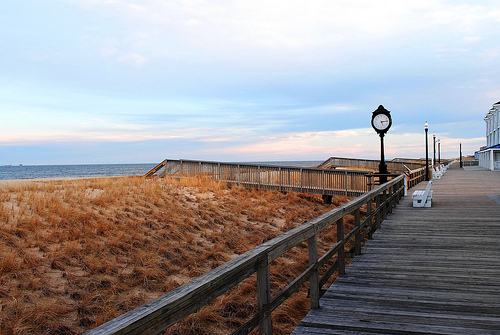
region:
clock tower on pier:
[365, 101, 391, 188]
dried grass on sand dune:
[5, 178, 317, 330]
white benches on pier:
[415, 155, 458, 210]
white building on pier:
[467, 102, 499, 170]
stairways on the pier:
[144, 151, 436, 196]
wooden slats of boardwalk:
[332, 145, 493, 332]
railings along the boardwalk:
[107, 151, 459, 333]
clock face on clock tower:
[372, 110, 389, 131]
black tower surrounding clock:
[373, 104, 389, 183]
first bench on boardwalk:
[398, 173, 435, 207]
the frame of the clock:
[368, 102, 397, 137]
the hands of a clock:
[377, 116, 391, 127]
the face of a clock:
[370, 113, 392, 132]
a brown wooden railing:
[73, 170, 411, 334]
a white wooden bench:
[406, 175, 439, 211]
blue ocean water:
[0, 157, 330, 185]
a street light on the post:
[421, 118, 432, 134]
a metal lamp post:
[421, 126, 431, 182]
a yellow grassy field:
[0, 173, 380, 334]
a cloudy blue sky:
[1, 0, 499, 165]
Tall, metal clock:
[367, 103, 390, 180]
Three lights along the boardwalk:
[423, 120, 444, 172]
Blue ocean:
[1, 160, 162, 177]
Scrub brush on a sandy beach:
[2, 170, 376, 332]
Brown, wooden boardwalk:
[87, 159, 498, 333]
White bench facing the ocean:
[411, 181, 434, 210]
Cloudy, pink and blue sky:
[0, 0, 497, 157]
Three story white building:
[473, 98, 498, 169]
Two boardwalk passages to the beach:
[137, 158, 419, 192]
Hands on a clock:
[379, 118, 388, 128]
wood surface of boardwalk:
[315, 155, 497, 333]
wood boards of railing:
[188, 176, 408, 333]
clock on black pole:
[371, 105, 396, 177]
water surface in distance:
[0, 157, 325, 182]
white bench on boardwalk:
[411, 181, 436, 213]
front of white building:
[478, 103, 497, 170]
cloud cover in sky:
[4, 2, 495, 161]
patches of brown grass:
[3, 177, 367, 331]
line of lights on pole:
[420, 119, 447, 177]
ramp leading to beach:
[160, 158, 398, 196]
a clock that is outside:
[269, 70, 428, 230]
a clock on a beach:
[326, 83, 456, 259]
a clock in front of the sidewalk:
[340, 119, 436, 259]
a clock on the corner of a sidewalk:
[261, 58, 496, 295]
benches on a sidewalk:
[391, 96, 482, 250]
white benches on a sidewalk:
[394, 97, 464, 252]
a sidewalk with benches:
[392, 86, 488, 258]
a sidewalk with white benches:
[392, 115, 499, 282]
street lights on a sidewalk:
[411, 98, 471, 225]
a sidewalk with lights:
[397, 88, 464, 208]